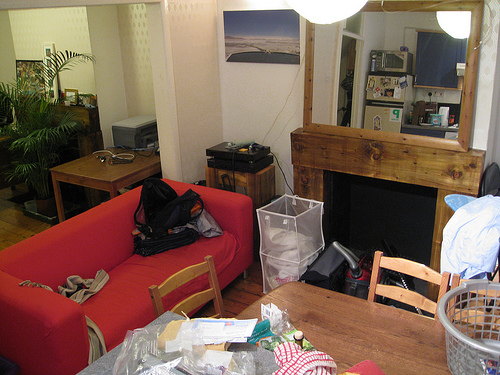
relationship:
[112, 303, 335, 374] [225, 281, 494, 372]
clutter on table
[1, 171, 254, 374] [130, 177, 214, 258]
couch has stuff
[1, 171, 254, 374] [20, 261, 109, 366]
couch has stuff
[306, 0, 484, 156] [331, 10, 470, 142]
mirror have reflection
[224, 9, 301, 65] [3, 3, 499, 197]
picture hanging in wall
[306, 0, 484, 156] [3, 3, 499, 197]
mirror of wall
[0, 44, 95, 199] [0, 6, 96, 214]
plant in corner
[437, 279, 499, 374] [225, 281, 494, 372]
laundry basket on table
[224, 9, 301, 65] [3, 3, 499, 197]
picture hanging on wall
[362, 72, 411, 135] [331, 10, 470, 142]
refrigerator in reflection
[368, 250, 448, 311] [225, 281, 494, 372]
chair by table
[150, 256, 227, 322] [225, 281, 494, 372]
chair by table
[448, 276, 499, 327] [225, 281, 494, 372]
chair by table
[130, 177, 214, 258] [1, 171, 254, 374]
backpack on couch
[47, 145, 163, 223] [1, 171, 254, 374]
table behind couch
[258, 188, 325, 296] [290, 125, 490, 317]
hamper by fireplace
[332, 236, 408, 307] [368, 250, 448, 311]
vacume behind chair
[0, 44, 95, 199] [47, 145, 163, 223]
plant behind table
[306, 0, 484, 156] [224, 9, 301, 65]
mirror next to picture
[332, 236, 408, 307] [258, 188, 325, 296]
vacume next to hamper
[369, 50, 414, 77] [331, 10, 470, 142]
microwave in reflection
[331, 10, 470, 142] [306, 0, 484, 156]
reflection in mirror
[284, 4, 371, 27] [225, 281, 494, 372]
light above table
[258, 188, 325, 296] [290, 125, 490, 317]
hamper beside fireplace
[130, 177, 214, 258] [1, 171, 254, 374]
stuff are on couch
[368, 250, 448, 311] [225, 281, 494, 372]
chair next to table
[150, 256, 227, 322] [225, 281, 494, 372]
chair next to table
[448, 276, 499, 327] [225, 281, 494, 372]
chair next to table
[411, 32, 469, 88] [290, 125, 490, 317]
window over fireplace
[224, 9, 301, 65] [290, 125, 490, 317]
picture next to fireplace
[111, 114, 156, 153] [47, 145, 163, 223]
printer on table